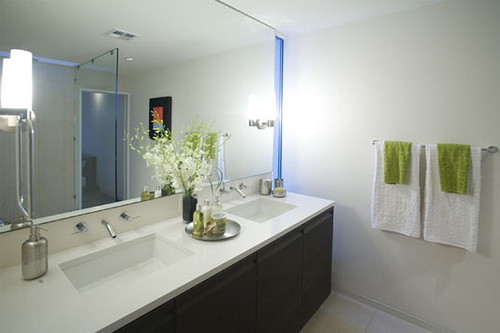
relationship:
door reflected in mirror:
[61, 79, 122, 212] [6, 14, 289, 185]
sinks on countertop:
[63, 194, 291, 304] [6, 171, 293, 332]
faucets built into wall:
[95, 213, 118, 246] [69, 174, 254, 244]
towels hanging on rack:
[377, 130, 470, 257] [383, 133, 477, 156]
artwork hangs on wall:
[148, 95, 174, 149] [126, 62, 271, 165]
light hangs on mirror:
[3, 36, 34, 125] [6, 14, 289, 185]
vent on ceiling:
[98, 27, 144, 47] [12, 3, 262, 56]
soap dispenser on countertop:
[24, 244, 52, 283] [6, 171, 293, 332]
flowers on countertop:
[126, 124, 229, 194] [6, 171, 293, 332]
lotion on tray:
[198, 195, 216, 217] [169, 199, 247, 257]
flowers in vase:
[126, 124, 229, 194] [178, 192, 200, 230]